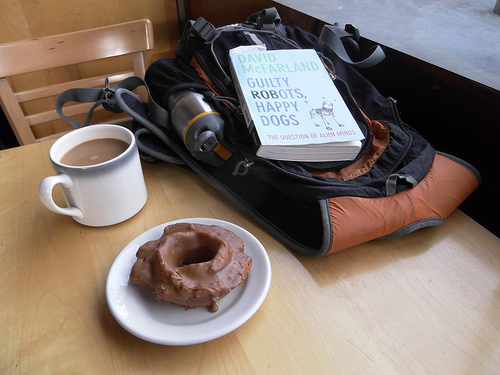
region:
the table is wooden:
[352, 270, 486, 349]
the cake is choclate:
[157, 230, 248, 297]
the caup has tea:
[49, 127, 129, 221]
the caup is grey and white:
[40, 140, 186, 217]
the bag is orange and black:
[166, 28, 486, 265]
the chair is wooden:
[26, 31, 152, 120]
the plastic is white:
[165, 88, 249, 155]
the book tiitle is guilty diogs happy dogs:
[228, 45, 379, 167]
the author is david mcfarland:
[241, 45, 323, 77]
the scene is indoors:
[10, 20, 496, 370]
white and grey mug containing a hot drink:
[33, 118, 150, 231]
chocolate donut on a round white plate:
[94, 212, 276, 351]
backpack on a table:
[45, 7, 485, 259]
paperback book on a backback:
[224, 41, 366, 166]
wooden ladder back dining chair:
[0, 16, 157, 150]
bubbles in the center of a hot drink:
[85, 152, 102, 164]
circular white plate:
[100, 214, 272, 351]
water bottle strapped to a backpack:
[165, 77, 231, 156]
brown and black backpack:
[50, 2, 481, 264]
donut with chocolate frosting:
[130, 217, 254, 317]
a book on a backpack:
[205, 26, 413, 221]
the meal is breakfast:
[53, 29, 420, 341]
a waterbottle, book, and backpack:
[166, 33, 417, 223]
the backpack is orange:
[167, 26, 427, 214]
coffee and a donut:
[33, 105, 311, 368]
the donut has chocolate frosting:
[131, 220, 235, 295]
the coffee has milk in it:
[37, 111, 157, 206]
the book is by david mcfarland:
[217, 33, 396, 179]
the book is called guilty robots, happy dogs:
[223, 35, 353, 157]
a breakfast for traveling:
[19, 34, 359, 362]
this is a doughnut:
[130, 225, 245, 294]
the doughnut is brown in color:
[136, 219, 243, 301]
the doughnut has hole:
[168, 235, 214, 265]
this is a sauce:
[147, 310, 182, 342]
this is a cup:
[78, 160, 133, 220]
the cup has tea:
[66, 137, 107, 159]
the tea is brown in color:
[73, 139, 112, 161]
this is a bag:
[347, 159, 412, 236]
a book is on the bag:
[239, 50, 336, 143]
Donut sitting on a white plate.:
[102, 215, 272, 349]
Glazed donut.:
[130, 219, 253, 315]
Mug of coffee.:
[38, 118, 149, 230]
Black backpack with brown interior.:
[55, 14, 485, 261]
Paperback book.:
[225, 42, 366, 167]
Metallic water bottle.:
[142, 58, 235, 171]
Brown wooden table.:
[0, 113, 498, 373]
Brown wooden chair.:
[1, 17, 159, 146]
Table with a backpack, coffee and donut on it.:
[2, 7, 499, 373]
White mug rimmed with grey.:
[38, 123, 148, 230]